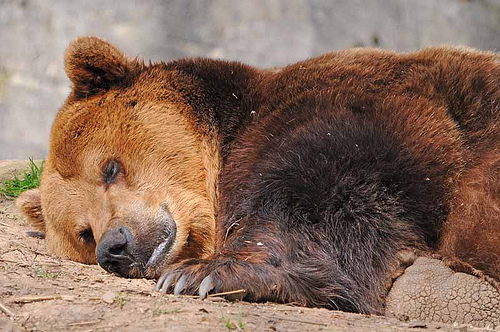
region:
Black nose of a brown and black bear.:
[91, 230, 129, 272]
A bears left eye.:
[102, 160, 118, 182]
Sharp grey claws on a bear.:
[153, 260, 216, 300]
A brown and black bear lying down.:
[18, 34, 499, 324]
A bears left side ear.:
[63, 38, 132, 93]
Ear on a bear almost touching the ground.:
[16, 192, 41, 227]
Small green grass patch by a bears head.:
[1, 155, 46, 195]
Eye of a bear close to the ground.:
[78, 227, 93, 242]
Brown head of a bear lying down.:
[15, 37, 224, 278]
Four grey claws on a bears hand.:
[152, 271, 214, 298]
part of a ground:
[61, 269, 86, 309]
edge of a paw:
[171, 258, 212, 299]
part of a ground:
[105, 283, 137, 323]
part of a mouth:
[142, 211, 182, 292]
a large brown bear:
[15, 36, 499, 313]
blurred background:
[3, 0, 495, 159]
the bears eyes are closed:
[16, 37, 494, 300]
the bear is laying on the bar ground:
[16, 35, 496, 330]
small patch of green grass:
[0, 157, 43, 200]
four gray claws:
[156, 261, 215, 301]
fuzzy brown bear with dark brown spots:
[16, 36, 492, 326]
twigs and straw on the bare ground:
[2, 203, 494, 328]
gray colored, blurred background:
[1, 1, 498, 159]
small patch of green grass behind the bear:
[1, 38, 498, 313]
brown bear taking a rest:
[30, 31, 497, 311]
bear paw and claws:
[155, 252, 275, 302]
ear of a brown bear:
[58, 33, 141, 94]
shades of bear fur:
[160, 78, 347, 203]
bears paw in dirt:
[150, 259, 274, 316]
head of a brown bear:
[23, 33, 199, 279]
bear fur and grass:
[8, 154, 53, 214]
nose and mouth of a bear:
[94, 197, 184, 278]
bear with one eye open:
[14, 24, 361, 308]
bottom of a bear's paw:
[366, 236, 496, 330]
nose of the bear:
[85, 220, 141, 282]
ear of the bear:
[59, 18, 150, 100]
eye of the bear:
[78, 140, 138, 201]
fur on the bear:
[256, 86, 398, 167]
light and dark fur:
[172, 62, 465, 232]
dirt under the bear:
[34, 273, 133, 329]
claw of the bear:
[161, 255, 226, 300]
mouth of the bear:
[133, 200, 198, 277]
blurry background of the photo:
[133, 4, 269, 49]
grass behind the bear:
[5, 158, 44, 190]